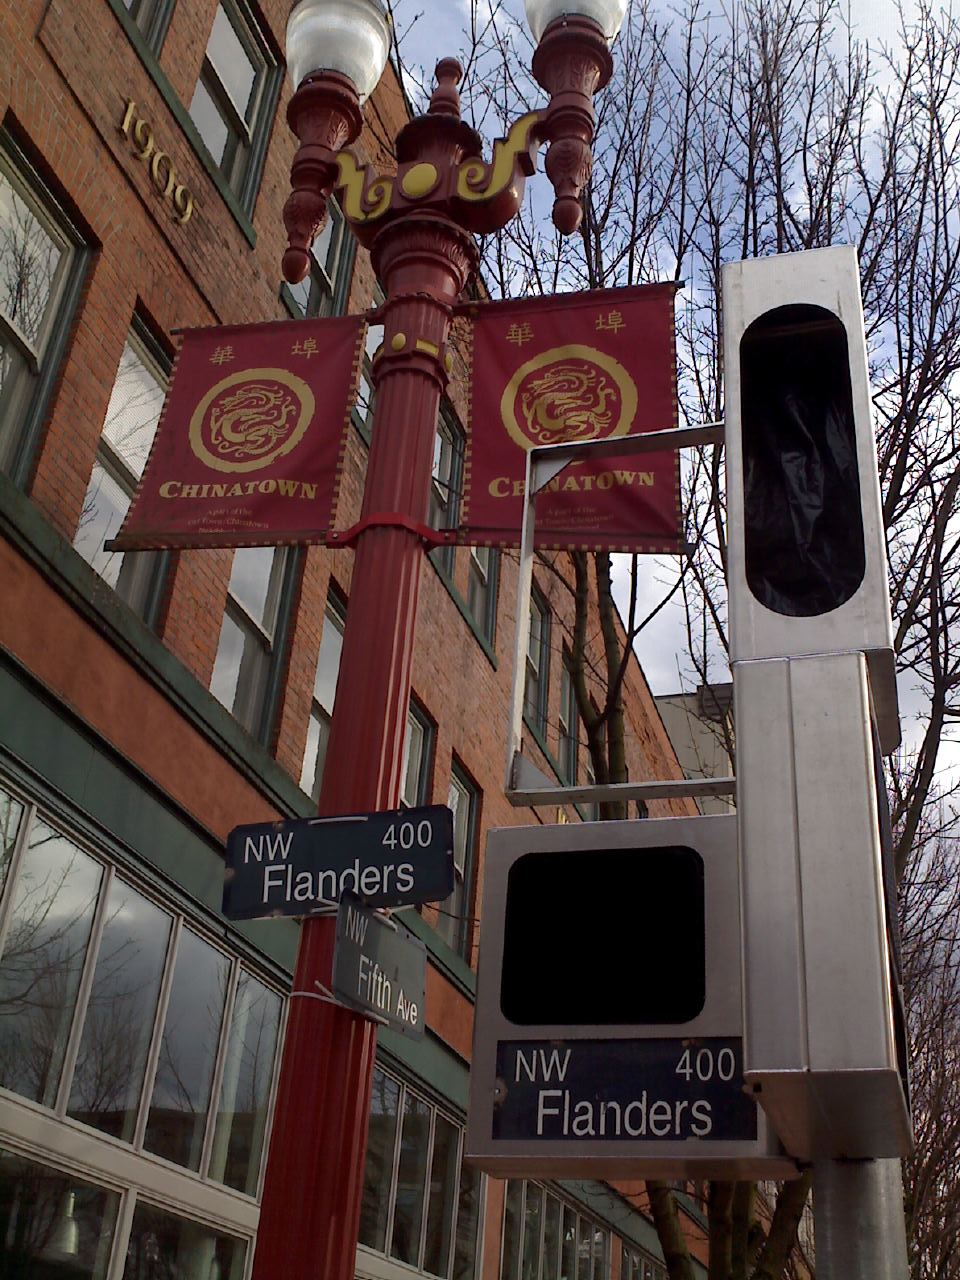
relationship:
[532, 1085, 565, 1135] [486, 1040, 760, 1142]
letter printed on sign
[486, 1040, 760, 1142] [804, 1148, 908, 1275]
sign mounted on pole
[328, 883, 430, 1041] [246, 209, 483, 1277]
sign mounted on pole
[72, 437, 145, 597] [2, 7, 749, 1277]
window on building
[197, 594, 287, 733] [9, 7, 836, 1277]
window on building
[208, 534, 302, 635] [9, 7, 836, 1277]
window on building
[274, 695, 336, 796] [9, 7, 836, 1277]
window on building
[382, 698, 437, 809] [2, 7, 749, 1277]
window on building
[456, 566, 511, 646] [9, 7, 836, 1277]
window on building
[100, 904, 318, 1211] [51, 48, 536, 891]
window on building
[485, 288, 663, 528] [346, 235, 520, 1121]
banner on pole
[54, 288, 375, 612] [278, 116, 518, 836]
banner on pole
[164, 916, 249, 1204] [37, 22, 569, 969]
window on building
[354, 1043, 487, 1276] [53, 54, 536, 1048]
window on building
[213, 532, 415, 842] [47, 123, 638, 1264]
window on building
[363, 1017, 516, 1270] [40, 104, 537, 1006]
window on building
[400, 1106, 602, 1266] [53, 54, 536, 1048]
window on building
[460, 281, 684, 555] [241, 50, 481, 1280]
banner on lamppost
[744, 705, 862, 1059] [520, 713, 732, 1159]
lamp on pole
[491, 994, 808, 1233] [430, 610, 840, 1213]
words on pole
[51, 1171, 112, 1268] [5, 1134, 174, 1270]
bell in window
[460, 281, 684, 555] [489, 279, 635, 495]
banner with logo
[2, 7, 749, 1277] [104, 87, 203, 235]
building with number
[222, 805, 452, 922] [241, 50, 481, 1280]
sign attached to lamppost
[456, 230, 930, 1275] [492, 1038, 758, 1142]
pole with sign